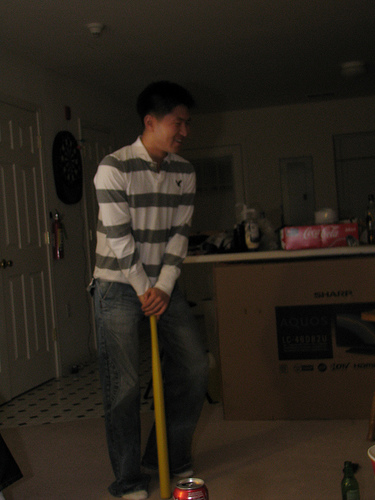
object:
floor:
[5, 423, 373, 496]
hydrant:
[48, 207, 70, 263]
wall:
[38, 72, 99, 378]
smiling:
[173, 136, 186, 146]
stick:
[148, 308, 173, 498]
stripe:
[100, 152, 195, 176]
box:
[212, 254, 374, 428]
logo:
[174, 178, 182, 189]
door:
[0, 102, 61, 407]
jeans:
[87, 280, 210, 499]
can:
[171, 475, 211, 495]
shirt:
[92, 134, 201, 301]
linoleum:
[52, 378, 104, 420]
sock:
[173, 468, 194, 479]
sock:
[120, 488, 148, 498]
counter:
[181, 243, 375, 265]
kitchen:
[0, 0, 375, 410]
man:
[75, 75, 235, 498]